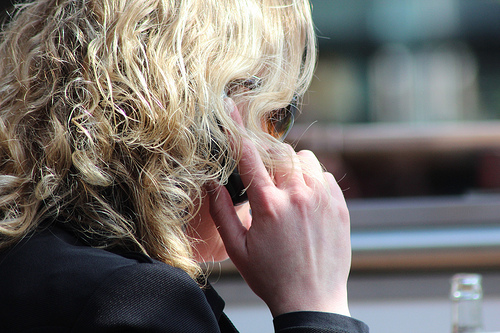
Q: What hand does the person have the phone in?
A: Right.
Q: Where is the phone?
A: The person's hand.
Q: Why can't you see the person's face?
A: They're turned away.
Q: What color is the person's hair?
A: Blonde.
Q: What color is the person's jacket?
A: Black.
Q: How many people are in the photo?
A: 1.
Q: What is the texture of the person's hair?
A: Wavy.